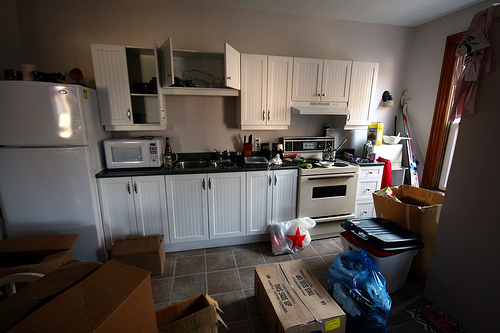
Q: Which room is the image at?
A: It is at the kitchen.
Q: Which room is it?
A: It is a kitchen.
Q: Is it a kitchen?
A: Yes, it is a kitchen.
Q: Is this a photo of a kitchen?
A: Yes, it is showing a kitchen.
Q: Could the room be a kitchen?
A: Yes, it is a kitchen.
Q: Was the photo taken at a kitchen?
A: Yes, it was taken in a kitchen.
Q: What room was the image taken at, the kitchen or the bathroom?
A: It was taken at the kitchen.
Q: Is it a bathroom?
A: No, it is a kitchen.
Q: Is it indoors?
A: Yes, it is indoors.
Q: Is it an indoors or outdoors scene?
A: It is indoors.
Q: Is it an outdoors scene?
A: No, it is indoors.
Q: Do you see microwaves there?
A: Yes, there is a microwave.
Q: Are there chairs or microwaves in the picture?
A: Yes, there is a microwave.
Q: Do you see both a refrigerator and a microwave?
A: Yes, there are both a microwave and a refrigerator.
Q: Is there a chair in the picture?
A: No, there are no chairs.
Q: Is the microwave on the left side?
A: Yes, the microwave is on the left of the image.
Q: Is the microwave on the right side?
A: No, the microwave is on the left of the image.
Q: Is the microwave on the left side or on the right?
A: The microwave is on the left of the image.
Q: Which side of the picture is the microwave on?
A: The microwave is on the left of the image.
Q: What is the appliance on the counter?
A: The appliance is a microwave.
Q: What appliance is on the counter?
A: The appliance is a microwave.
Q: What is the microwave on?
A: The microwave is on the counter.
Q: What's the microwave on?
A: The microwave is on the counter.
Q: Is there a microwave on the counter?
A: Yes, there is a microwave on the counter.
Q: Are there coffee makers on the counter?
A: No, there is a microwave on the counter.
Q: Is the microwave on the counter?
A: Yes, the microwave is on the counter.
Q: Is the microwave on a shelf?
A: No, the microwave is on the counter.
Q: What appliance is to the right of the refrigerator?
A: The appliance is a microwave.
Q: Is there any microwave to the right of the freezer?
A: Yes, there is a microwave to the right of the freezer.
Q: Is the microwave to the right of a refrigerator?
A: Yes, the microwave is to the right of a refrigerator.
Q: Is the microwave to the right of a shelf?
A: No, the microwave is to the right of a refrigerator.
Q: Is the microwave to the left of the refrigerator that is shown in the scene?
A: No, the microwave is to the right of the refrigerator.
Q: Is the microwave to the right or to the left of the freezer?
A: The microwave is to the right of the freezer.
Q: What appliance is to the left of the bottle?
A: The appliance is a microwave.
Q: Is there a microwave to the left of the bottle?
A: Yes, there is a microwave to the left of the bottle.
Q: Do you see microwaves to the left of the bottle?
A: Yes, there is a microwave to the left of the bottle.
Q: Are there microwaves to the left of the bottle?
A: Yes, there is a microwave to the left of the bottle.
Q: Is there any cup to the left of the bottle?
A: No, there is a microwave to the left of the bottle.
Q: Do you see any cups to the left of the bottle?
A: No, there is a microwave to the left of the bottle.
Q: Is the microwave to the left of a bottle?
A: Yes, the microwave is to the left of a bottle.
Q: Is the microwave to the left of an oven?
A: No, the microwave is to the left of a bottle.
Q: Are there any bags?
A: Yes, there is a bag.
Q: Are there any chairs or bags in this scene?
A: Yes, there is a bag.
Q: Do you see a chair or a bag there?
A: Yes, there is a bag.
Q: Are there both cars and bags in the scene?
A: No, there is a bag but no cars.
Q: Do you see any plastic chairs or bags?
A: Yes, there is a plastic bag.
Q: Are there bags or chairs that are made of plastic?
A: Yes, the bag is made of plastic.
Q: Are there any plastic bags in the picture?
A: Yes, there is a bag that is made of plastic.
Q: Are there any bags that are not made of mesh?
A: Yes, there is a bag that is made of plastic.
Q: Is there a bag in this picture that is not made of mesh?
A: Yes, there is a bag that is made of plastic.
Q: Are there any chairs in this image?
A: No, there are no chairs.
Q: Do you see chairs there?
A: No, there are no chairs.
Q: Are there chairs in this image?
A: No, there are no chairs.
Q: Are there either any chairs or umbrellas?
A: No, there are no chairs or umbrellas.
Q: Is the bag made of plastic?
A: Yes, the bag is made of plastic.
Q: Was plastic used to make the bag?
A: Yes, the bag is made of plastic.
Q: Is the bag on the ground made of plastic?
A: Yes, the bag is made of plastic.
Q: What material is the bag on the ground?
A: The bag is made of plastic.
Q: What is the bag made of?
A: The bag is made of plastic.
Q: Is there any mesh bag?
A: No, there is a bag but it is made of plastic.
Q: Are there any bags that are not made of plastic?
A: No, there is a bag but it is made of plastic.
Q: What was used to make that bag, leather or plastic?
A: The bag is made of plastic.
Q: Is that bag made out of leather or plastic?
A: The bag is made of plastic.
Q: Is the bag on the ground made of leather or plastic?
A: The bag is made of plastic.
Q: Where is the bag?
A: The bag is on the ground.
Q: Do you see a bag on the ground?
A: Yes, there is a bag on the ground.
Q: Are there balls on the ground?
A: No, there is a bag on the ground.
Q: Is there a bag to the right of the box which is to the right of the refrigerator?
A: Yes, there is a bag to the right of the box.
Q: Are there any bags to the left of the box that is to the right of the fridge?
A: No, the bag is to the right of the box.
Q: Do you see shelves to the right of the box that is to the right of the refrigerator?
A: No, there is a bag to the right of the box.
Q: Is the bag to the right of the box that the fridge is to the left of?
A: Yes, the bag is to the right of the box.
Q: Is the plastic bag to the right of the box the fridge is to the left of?
A: Yes, the bag is to the right of the box.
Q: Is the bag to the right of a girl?
A: No, the bag is to the right of the box.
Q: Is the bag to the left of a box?
A: No, the bag is to the right of a box.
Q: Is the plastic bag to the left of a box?
A: No, the bag is to the right of a box.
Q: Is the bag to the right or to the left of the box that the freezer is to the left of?
A: The bag is to the right of the box.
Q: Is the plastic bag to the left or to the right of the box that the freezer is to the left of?
A: The bag is to the right of the box.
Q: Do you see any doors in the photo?
A: Yes, there are doors.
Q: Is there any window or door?
A: Yes, there are doors.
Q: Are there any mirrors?
A: No, there are no mirrors.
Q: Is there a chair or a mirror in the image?
A: No, there are no mirrors or chairs.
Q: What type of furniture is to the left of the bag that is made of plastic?
A: The piece of furniture is a cupboard.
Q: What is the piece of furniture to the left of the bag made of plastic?
A: The piece of furniture is a cupboard.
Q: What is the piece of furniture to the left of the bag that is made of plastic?
A: The piece of furniture is a cupboard.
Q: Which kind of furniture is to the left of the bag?
A: The piece of furniture is a cupboard.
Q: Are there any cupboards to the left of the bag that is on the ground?
A: Yes, there is a cupboard to the left of the bag.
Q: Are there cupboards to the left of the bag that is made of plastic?
A: Yes, there is a cupboard to the left of the bag.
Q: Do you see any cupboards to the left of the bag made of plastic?
A: Yes, there is a cupboard to the left of the bag.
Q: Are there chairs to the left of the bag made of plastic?
A: No, there is a cupboard to the left of the bag.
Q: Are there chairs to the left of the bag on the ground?
A: No, there is a cupboard to the left of the bag.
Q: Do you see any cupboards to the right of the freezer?
A: Yes, there is a cupboard to the right of the freezer.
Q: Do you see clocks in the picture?
A: No, there are no clocks.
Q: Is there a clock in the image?
A: No, there are no clocks.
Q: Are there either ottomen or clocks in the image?
A: No, there are no clocks or ottomen.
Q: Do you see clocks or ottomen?
A: No, there are no clocks or ottomen.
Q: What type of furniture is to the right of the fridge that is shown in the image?
A: The piece of furniture is a cupboard.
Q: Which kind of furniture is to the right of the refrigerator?
A: The piece of furniture is a cupboard.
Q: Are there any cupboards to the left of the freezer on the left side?
A: No, the cupboard is to the right of the refrigerator.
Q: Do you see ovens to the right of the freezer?
A: No, there is a cupboard to the right of the freezer.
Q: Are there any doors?
A: Yes, there is a door.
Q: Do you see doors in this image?
A: Yes, there is a door.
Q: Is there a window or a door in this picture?
A: Yes, there is a door.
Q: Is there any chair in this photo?
A: No, there are no chairs.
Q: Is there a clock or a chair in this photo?
A: No, there are no chairs or clocks.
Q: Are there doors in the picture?
A: Yes, there is a door.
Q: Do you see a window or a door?
A: Yes, there is a door.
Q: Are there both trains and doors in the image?
A: No, there is a door but no trains.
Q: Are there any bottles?
A: Yes, there is a bottle.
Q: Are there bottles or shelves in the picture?
A: Yes, there is a bottle.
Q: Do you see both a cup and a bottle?
A: No, there is a bottle but no cups.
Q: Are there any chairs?
A: No, there are no chairs.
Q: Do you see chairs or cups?
A: No, there are no chairs or cups.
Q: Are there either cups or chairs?
A: No, there are no chairs or cups.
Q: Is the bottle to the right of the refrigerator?
A: Yes, the bottle is to the right of the refrigerator.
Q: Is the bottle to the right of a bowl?
A: No, the bottle is to the right of the refrigerator.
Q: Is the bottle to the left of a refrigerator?
A: No, the bottle is to the right of a refrigerator.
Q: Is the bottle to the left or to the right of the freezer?
A: The bottle is to the right of the freezer.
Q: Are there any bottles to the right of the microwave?
A: Yes, there is a bottle to the right of the microwave.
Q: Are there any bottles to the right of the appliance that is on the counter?
A: Yes, there is a bottle to the right of the microwave.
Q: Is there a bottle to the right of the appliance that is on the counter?
A: Yes, there is a bottle to the right of the microwave.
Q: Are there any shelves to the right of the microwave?
A: No, there is a bottle to the right of the microwave.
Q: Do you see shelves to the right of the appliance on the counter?
A: No, there is a bottle to the right of the microwave.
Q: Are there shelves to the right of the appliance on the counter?
A: No, there is a bottle to the right of the microwave.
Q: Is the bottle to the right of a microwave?
A: Yes, the bottle is to the right of a microwave.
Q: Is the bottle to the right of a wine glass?
A: No, the bottle is to the right of a microwave.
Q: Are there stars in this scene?
A: Yes, there is a star.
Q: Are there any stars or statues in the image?
A: Yes, there is a star.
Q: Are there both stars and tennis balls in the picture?
A: No, there is a star but no tennis balls.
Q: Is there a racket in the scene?
A: No, there are no rackets.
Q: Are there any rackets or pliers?
A: No, there are no rackets or pliers.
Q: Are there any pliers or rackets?
A: No, there are no rackets or pliers.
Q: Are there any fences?
A: No, there are no fences.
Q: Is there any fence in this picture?
A: No, there are no fences.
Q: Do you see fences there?
A: No, there are no fences.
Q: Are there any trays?
A: No, there are no trays.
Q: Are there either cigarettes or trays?
A: No, there are no trays or cigarettes.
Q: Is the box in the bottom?
A: Yes, the box is in the bottom of the image.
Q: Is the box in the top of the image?
A: No, the box is in the bottom of the image.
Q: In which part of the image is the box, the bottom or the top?
A: The box is in the bottom of the image.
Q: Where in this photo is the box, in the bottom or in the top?
A: The box is in the bottom of the image.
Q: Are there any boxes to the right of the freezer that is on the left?
A: Yes, there is a box to the right of the freezer.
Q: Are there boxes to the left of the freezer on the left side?
A: No, the box is to the right of the fridge.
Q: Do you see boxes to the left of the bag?
A: Yes, there is a box to the left of the bag.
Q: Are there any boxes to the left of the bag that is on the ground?
A: Yes, there is a box to the left of the bag.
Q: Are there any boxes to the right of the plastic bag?
A: No, the box is to the left of the bag.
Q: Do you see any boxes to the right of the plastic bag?
A: No, the box is to the left of the bag.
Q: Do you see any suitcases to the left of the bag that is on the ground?
A: No, there is a box to the left of the bag.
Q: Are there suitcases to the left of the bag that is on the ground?
A: No, there is a box to the left of the bag.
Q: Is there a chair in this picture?
A: No, there are no chairs.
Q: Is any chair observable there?
A: No, there are no chairs.